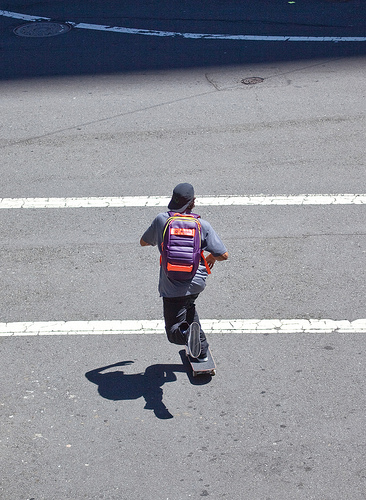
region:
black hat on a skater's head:
[165, 182, 196, 214]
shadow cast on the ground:
[82, 357, 185, 419]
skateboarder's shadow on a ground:
[84, 359, 190, 418]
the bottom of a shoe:
[185, 320, 204, 358]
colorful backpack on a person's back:
[158, 210, 203, 281]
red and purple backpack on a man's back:
[159, 209, 207, 281]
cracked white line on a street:
[0, 317, 363, 337]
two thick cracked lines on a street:
[0, 191, 364, 337]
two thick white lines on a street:
[1, 191, 364, 337]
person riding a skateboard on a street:
[138, 182, 231, 377]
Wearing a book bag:
[141, 210, 221, 286]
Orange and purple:
[152, 206, 221, 292]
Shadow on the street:
[65, 337, 227, 428]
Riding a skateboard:
[151, 314, 232, 389]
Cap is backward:
[159, 175, 203, 213]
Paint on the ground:
[0, 178, 364, 357]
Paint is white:
[4, 182, 363, 347]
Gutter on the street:
[5, 6, 86, 63]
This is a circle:
[6, 10, 85, 53]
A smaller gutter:
[232, 66, 268, 94]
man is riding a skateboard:
[115, 182, 237, 437]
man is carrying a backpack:
[135, 171, 225, 425]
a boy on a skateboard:
[133, 140, 297, 385]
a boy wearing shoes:
[132, 308, 254, 408]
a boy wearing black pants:
[135, 292, 255, 404]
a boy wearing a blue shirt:
[132, 128, 316, 356]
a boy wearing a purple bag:
[88, 131, 290, 345]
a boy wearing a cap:
[148, 159, 221, 232]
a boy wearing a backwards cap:
[135, 174, 234, 237]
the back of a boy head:
[152, 144, 252, 237]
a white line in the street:
[17, 257, 214, 347]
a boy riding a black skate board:
[151, 296, 261, 399]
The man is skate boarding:
[138, 179, 230, 384]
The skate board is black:
[185, 348, 218, 383]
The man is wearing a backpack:
[140, 181, 227, 292]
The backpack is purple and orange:
[161, 213, 202, 275]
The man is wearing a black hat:
[166, 181, 197, 213]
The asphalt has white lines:
[0, 17, 362, 367]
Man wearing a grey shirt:
[140, 184, 224, 299]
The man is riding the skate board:
[141, 182, 229, 382]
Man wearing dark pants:
[162, 294, 208, 361]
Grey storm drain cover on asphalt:
[13, 13, 70, 38]